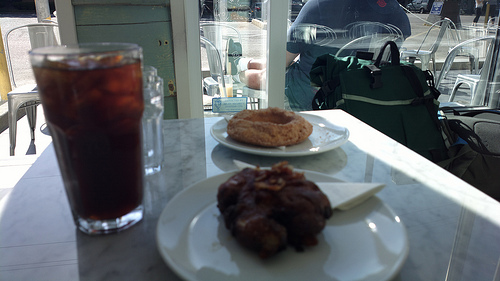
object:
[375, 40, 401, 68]
strap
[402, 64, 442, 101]
strap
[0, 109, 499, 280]
table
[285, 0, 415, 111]
person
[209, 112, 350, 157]
plate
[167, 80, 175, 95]
hole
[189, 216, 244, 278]
light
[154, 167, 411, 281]
plate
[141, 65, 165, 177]
glass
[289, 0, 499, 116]
window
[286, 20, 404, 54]
glare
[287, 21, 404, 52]
reflection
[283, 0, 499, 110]
glass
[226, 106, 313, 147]
donut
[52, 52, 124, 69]
ice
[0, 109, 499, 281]
countertop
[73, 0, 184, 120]
green wall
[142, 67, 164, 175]
clear glass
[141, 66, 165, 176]
empty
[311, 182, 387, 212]
napkin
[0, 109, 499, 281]
table top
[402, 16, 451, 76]
chair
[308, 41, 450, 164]
bag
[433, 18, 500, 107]
chair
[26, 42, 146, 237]
glass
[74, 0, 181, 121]
paint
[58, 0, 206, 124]
wall